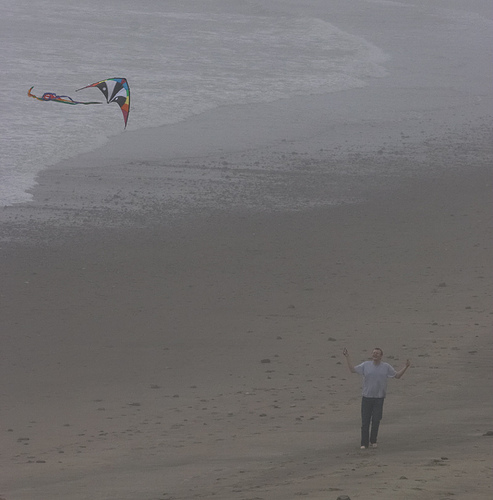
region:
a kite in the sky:
[34, 47, 165, 144]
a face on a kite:
[79, 59, 153, 135]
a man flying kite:
[46, 57, 481, 493]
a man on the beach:
[301, 290, 483, 490]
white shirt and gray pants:
[323, 334, 431, 462]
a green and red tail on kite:
[25, 74, 122, 121]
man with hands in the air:
[310, 305, 451, 486]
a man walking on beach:
[283, 307, 445, 462]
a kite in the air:
[30, 34, 176, 160]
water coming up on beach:
[44, 26, 406, 204]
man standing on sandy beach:
[348, 325, 392, 457]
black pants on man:
[351, 396, 379, 445]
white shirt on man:
[354, 358, 392, 398]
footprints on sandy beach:
[266, 351, 319, 415]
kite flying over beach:
[72, 68, 139, 120]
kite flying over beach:
[3, 89, 91, 107]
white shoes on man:
[357, 437, 376, 454]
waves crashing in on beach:
[0, 23, 272, 216]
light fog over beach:
[62, 129, 492, 435]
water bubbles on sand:
[214, 137, 292, 164]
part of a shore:
[287, 303, 288, 309]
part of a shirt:
[372, 397, 373, 401]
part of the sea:
[228, 315, 239, 337]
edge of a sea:
[258, 279, 261, 284]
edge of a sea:
[150, 357, 170, 406]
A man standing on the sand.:
[343, 346, 410, 450]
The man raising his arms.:
[335, 345, 412, 379]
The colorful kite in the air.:
[25, 72, 140, 126]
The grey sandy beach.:
[97, 271, 268, 333]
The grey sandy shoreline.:
[131, 102, 297, 166]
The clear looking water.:
[149, 40, 329, 82]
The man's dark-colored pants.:
[356, 394, 385, 446]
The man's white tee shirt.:
[353, 359, 398, 399]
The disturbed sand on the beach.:
[156, 358, 315, 436]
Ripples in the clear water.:
[196, 71, 264, 99]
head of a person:
[371, 343, 386, 358]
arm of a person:
[342, 356, 356, 369]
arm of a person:
[395, 365, 411, 374]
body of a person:
[352, 374, 394, 397]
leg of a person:
[355, 409, 371, 440]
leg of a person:
[368, 402, 384, 439]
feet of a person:
[358, 440, 369, 449]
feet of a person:
[369, 445, 376, 447]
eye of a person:
[367, 347, 380, 353]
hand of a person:
[340, 340, 354, 354]